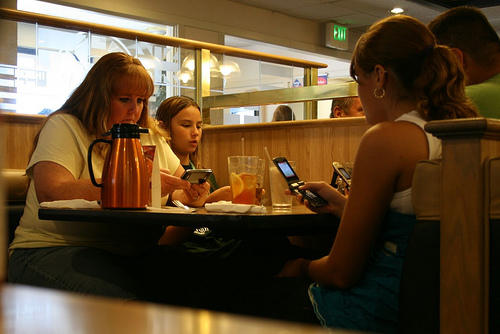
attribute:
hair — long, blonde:
[158, 85, 210, 182]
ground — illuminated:
[425, 147, 442, 164]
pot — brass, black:
[83, 118, 159, 214]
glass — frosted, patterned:
[24, 30, 94, 80]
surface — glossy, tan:
[2, 282, 336, 332]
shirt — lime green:
[462, 74, 498, 119]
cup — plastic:
[241, 154, 268, 206]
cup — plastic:
[225, 151, 257, 208]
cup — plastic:
[268, 154, 298, 203]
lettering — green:
[332, 24, 347, 43]